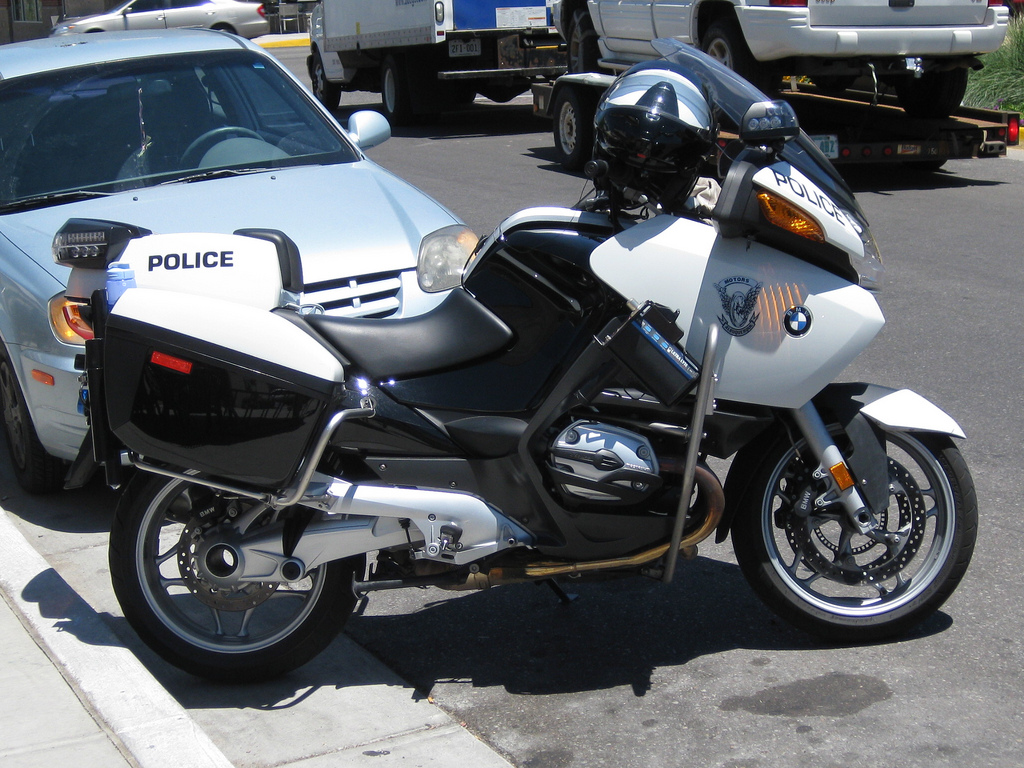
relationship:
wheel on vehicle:
[371, 46, 445, 142] [299, 6, 557, 123]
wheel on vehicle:
[302, 43, 350, 132] [303, 0, 572, 132]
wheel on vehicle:
[545, 75, 603, 178] [536, 0, 1021, 186]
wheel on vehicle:
[715, 374, 990, 653] [46, 31, 975, 678]